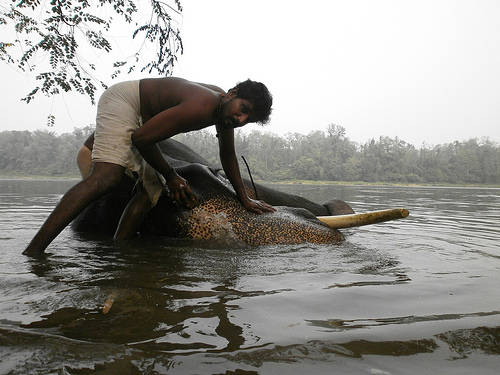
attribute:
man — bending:
[22, 79, 275, 257]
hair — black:
[234, 78, 274, 127]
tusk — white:
[315, 207, 410, 231]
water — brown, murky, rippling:
[0, 178, 498, 374]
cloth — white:
[91, 78, 166, 206]